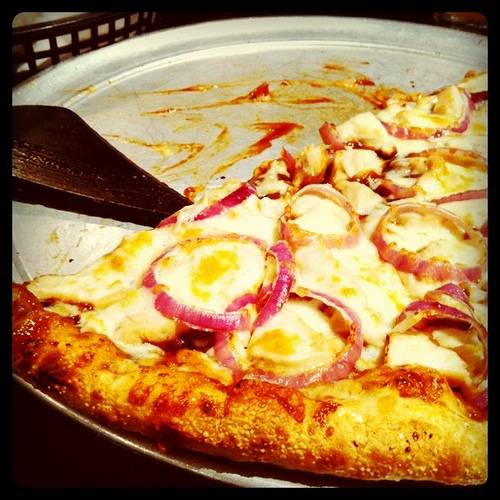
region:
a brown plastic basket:
[11, 5, 154, 80]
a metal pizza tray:
[10, 16, 486, 487]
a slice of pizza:
[10, 157, 293, 457]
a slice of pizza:
[211, 144, 485, 485]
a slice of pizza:
[326, 169, 486, 384]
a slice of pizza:
[316, 69, 488, 171]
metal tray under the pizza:
[12, 15, 487, 488]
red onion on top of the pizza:
[140, 230, 297, 325]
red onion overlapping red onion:
[217, 282, 362, 383]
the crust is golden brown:
[9, 280, 498, 498]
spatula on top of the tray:
[12, 105, 193, 222]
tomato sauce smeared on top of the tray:
[136, 62, 412, 198]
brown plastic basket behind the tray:
[8, 8, 162, 82]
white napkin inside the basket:
[15, 12, 152, 72]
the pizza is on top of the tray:
[12, 63, 497, 496]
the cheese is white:
[30, 72, 489, 390]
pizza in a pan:
[12, 100, 404, 360]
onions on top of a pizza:
[166, 217, 295, 345]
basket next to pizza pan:
[19, 19, 119, 64]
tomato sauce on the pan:
[202, 53, 316, 145]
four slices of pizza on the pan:
[136, 85, 465, 321]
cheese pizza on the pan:
[70, 43, 462, 448]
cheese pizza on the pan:
[327, 71, 494, 365]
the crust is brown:
[154, 387, 451, 481]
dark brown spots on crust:
[35, 331, 356, 451]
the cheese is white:
[306, 247, 403, 317]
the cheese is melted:
[315, 250, 410, 335]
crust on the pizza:
[53, 269, 467, 480]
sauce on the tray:
[148, 72, 349, 165]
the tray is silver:
[242, 25, 451, 84]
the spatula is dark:
[12, 102, 164, 227]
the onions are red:
[154, 242, 333, 359]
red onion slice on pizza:
[137, 232, 262, 331]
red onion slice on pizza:
[247, 237, 294, 333]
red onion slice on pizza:
[217, 284, 361, 386]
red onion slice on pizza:
[380, 299, 487, 385]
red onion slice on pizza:
[422, 282, 481, 319]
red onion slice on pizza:
[278, 182, 361, 245]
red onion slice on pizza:
[372, 202, 487, 280]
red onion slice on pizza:
[372, 85, 478, 139]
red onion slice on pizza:
[428, 186, 487, 205]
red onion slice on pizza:
[411, 145, 489, 164]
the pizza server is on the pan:
[19, 92, 189, 217]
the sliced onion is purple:
[153, 225, 295, 327]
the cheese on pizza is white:
[116, 93, 485, 386]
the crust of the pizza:
[18, 287, 476, 478]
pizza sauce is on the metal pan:
[153, 63, 327, 163]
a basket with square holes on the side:
[20, 15, 158, 69]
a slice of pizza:
[11, 145, 302, 409]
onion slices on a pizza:
[129, 211, 357, 382]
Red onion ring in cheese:
[149, 229, 291, 331]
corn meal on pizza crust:
[41, 366, 334, 468]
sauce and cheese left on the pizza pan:
[88, 42, 395, 165]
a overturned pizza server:
[15, 102, 192, 221]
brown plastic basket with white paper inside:
[12, 11, 162, 80]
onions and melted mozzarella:
[246, 93, 493, 356]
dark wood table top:
[12, 395, 210, 499]